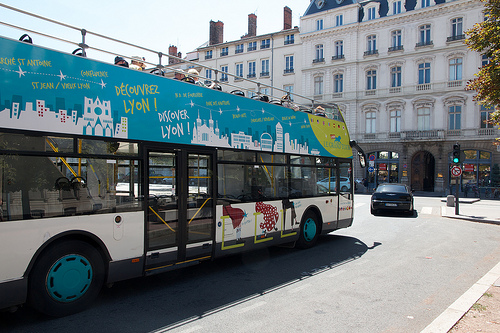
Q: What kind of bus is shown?
A: A double decker.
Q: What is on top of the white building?
A: Chimneys.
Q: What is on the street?
A: A bus.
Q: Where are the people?
A: On top of the bus.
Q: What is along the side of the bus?
A: A railing.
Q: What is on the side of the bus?
A: A blue sign.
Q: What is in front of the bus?
A: A black car.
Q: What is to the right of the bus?
A: A tree.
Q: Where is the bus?
A: On a concrete roadway.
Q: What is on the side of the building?
A: Windows.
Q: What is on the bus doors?
A: A black frame.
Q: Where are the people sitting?
A: On top of the bus.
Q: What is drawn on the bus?
A: The cityscape.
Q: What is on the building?
A: Numerous chimneys.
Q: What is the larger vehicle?
A: Bus.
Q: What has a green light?
A: Traffic signal.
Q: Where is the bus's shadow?
A: On the road.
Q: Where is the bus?
A: On the road.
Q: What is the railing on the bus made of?
A: Metal.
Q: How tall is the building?
A: Five stories.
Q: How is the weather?
A: Clear.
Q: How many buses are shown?
A: One.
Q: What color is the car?
A: Black.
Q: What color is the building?
A: White.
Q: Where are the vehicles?
A: The road.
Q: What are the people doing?
A: Sitting.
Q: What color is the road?
A: Gray.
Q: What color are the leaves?
A: Green.